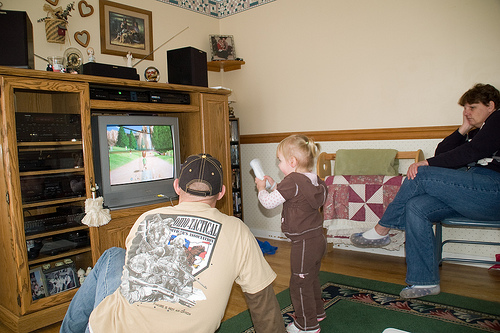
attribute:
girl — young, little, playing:
[256, 135, 327, 332]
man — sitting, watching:
[62, 154, 288, 331]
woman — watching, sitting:
[351, 83, 500, 298]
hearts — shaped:
[73, 31, 92, 49]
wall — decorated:
[19, 1, 220, 95]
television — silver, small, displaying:
[93, 114, 182, 209]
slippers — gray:
[351, 232, 440, 299]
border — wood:
[235, 125, 472, 142]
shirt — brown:
[278, 174, 326, 243]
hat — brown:
[177, 154, 224, 195]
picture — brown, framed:
[99, 2, 155, 61]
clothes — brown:
[276, 172, 328, 330]